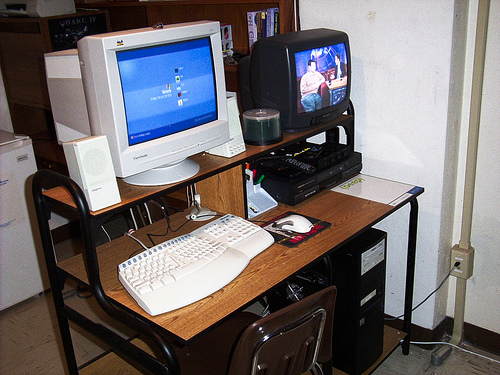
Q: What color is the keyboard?
A: White.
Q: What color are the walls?
A: White.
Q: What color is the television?
A: Black.